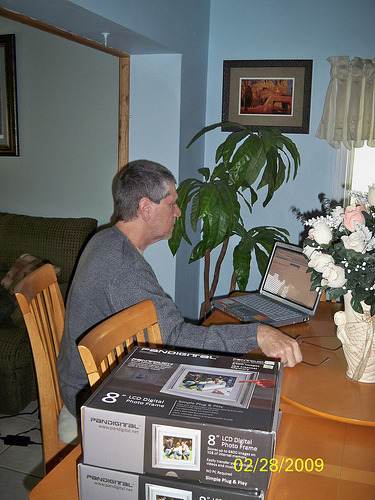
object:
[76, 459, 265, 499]
box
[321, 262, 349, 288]
flower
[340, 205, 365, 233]
flower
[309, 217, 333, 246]
flower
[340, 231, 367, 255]
flower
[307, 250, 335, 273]
flower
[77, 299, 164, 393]
chair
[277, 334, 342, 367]
glasses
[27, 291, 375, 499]
table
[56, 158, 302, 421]
man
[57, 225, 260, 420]
sweatshirt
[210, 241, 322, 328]
laptop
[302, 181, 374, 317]
bouquet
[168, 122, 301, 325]
houseplant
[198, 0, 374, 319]
wall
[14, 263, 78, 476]
chair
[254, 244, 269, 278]
leaf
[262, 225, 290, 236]
leaf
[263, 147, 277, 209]
leaf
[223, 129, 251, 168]
leaf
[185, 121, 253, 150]
leaf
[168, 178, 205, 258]
leaf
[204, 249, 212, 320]
stem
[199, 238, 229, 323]
stem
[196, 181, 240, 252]
leaf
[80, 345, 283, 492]
box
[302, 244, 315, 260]
rose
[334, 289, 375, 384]
vase